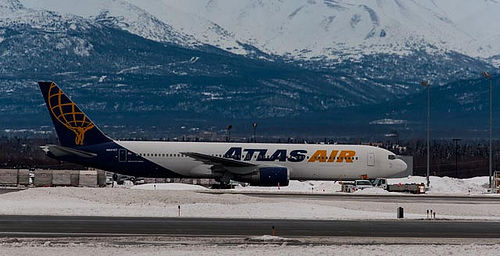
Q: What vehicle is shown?
A: A plane.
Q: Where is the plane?
A: At an airport.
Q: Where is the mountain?
A: Behind the airport.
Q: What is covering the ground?
A: Snow.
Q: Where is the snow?
A: On the ground.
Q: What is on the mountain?
A: Snow.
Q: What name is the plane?
A: Atlas air.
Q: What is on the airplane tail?
A: An atlas.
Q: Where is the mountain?
A: In the distance.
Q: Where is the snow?
A: On the mountain.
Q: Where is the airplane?
A: On the runway.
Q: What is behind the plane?
A: A mountain.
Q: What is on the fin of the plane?
A: A globe.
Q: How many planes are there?
A: One.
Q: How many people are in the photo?
A: None.